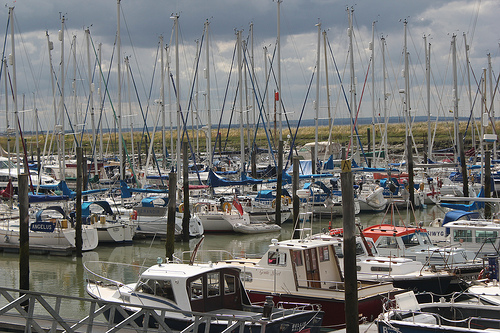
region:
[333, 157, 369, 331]
a wooden pole next to a boat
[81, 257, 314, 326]
a small white and brown boat parked by another boat.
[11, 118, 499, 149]
a grassy field behind the boats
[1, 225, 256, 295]
the water that boats are parked in.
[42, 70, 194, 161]
metal poles stuck on the many boats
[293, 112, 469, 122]
a mountain behind the grassy field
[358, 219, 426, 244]
the red roof of a boat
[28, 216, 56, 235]
a sign saying the name of a boat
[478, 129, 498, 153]
a light on the pole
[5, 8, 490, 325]
hundreds of boats at a marina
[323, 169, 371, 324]
a wood piling at the marina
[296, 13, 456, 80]
a somewhat dark cloudy sky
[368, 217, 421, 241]
the red top of a boat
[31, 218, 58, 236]
a sign on the side of a boat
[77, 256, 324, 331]
a small yacht at the marina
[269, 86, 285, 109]
a small red flag type thing on a pole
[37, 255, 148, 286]
brownish green water at the marina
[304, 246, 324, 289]
doors on the cabin of a yacht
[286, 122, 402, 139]
lots of weeds growing beyond the marina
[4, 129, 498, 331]
multiple boats in bay area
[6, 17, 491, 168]
mast poles on boats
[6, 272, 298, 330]
walkway to boats in docks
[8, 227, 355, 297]
backwaters of ocean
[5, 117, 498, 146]
grass on land divider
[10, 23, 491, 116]
cloud covered sky in background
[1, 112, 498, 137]
small area of visible ocean in background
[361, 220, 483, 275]
small boat with red roof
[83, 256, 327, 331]
closest boat with white roof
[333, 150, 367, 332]
secure post with an "a" on top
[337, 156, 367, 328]
a long wooden pole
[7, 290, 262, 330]
a wooden fence by a walkway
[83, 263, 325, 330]
a brown and white boat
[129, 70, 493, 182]
the poles on top of the boats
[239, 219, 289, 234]
a life boat in the water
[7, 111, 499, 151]
a grassy field behind the water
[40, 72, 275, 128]
the cloudy sky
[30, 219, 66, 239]
the name tag of a boat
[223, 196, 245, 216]
a flag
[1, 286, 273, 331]
metal railing leading to the boats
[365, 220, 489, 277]
a boat with a red roof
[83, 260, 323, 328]
a black and white boat is parked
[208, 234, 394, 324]
a brown and white boat is parked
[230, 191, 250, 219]
a red flag on the back of a boat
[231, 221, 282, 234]
an inflatable dingy tied to the back of a boat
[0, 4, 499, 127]
a cloudy sky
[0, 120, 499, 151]
a field of grass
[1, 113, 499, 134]
dark hills in the background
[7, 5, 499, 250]
rows of parked boate